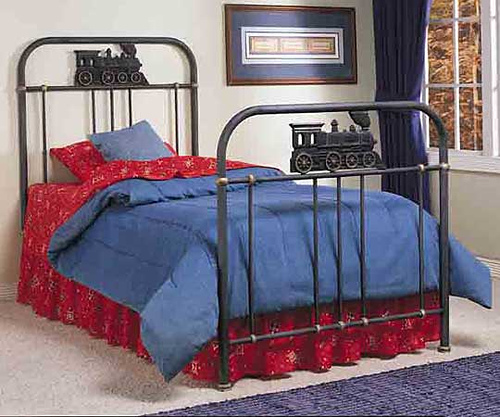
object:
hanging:
[225, 7, 364, 88]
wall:
[214, 5, 391, 127]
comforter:
[92, 165, 211, 299]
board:
[223, 102, 452, 358]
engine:
[68, 36, 155, 94]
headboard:
[8, 31, 204, 176]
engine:
[285, 104, 387, 178]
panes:
[419, 0, 497, 169]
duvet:
[39, 164, 488, 385]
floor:
[4, 349, 140, 414]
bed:
[12, 27, 455, 389]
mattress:
[12, 149, 466, 390]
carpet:
[13, 344, 145, 414]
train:
[68, 36, 157, 90]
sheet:
[17, 182, 80, 252]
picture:
[218, 0, 359, 89]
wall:
[4, 4, 216, 36]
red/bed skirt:
[201, 290, 446, 383]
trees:
[426, 2, 481, 151]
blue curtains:
[372, 1, 431, 215]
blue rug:
[157, 359, 482, 414]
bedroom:
[3, 1, 484, 398]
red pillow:
[49, 136, 177, 178]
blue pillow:
[86, 119, 174, 163]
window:
[420, 0, 483, 152]